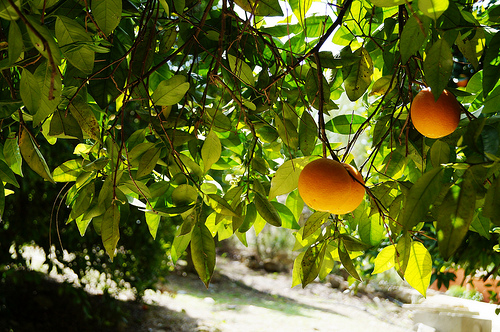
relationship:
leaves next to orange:
[23, 10, 257, 173] [298, 154, 377, 221]